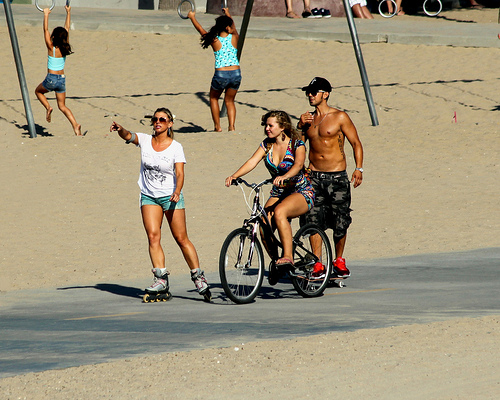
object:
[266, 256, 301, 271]
flip flops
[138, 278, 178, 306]
foot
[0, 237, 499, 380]
walkway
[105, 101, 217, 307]
woman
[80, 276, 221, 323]
roller-blades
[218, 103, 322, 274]
woman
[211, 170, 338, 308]
bicycle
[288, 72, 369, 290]
man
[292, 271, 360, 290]
skateboard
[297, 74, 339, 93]
cap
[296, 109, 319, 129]
right hand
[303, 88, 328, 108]
face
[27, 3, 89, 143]
woman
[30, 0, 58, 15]
metal rings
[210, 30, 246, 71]
top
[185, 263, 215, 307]
skates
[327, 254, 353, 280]
sneakers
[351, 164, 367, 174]
watch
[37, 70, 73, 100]
short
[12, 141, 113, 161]
sand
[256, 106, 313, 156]
hair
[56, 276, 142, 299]
shadow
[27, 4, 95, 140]
girl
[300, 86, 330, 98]
sunglasses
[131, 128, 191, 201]
shirt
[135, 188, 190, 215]
shorts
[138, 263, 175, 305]
rollerskate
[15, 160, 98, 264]
sand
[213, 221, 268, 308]
front tire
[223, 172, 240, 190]
right hand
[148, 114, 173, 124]
sunglasses